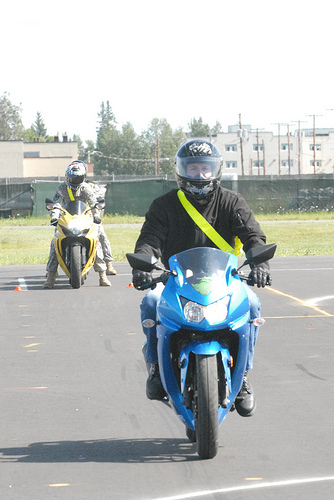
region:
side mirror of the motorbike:
[249, 245, 281, 266]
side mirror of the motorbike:
[125, 247, 160, 273]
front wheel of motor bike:
[192, 347, 230, 470]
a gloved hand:
[246, 265, 278, 291]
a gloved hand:
[132, 266, 164, 297]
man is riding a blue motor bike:
[121, 120, 287, 472]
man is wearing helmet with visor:
[174, 143, 228, 195]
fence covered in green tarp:
[237, 179, 330, 208]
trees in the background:
[100, 106, 170, 172]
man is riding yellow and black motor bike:
[45, 160, 107, 286]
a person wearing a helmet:
[172, 142, 227, 195]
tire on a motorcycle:
[186, 350, 224, 459]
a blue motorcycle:
[153, 240, 263, 462]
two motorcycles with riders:
[42, 137, 303, 430]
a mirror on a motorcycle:
[121, 251, 179, 277]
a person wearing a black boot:
[235, 371, 255, 414]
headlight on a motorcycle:
[178, 294, 230, 325]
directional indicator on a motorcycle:
[142, 315, 161, 329]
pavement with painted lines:
[285, 281, 327, 331]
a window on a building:
[280, 140, 290, 150]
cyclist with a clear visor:
[122, 134, 279, 463]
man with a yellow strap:
[124, 136, 278, 288]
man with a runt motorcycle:
[122, 131, 283, 462]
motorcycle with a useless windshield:
[123, 129, 277, 454]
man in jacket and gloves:
[125, 135, 292, 460]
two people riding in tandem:
[28, 132, 123, 299]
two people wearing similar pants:
[35, 154, 116, 296]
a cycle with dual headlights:
[119, 238, 284, 461]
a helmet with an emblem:
[160, 132, 232, 198]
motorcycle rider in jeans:
[122, 135, 290, 462]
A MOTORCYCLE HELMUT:
[171, 132, 227, 210]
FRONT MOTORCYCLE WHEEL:
[189, 343, 242, 460]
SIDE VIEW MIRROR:
[123, 248, 179, 279]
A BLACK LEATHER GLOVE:
[245, 249, 283, 289]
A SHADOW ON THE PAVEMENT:
[3, 430, 182, 474]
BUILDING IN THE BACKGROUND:
[224, 131, 330, 174]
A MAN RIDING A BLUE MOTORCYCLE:
[120, 133, 278, 467]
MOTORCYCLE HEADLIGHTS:
[179, 293, 230, 324]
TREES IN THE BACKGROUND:
[92, 91, 142, 176]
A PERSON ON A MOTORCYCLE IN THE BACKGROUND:
[34, 157, 128, 292]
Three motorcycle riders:
[22, 129, 308, 457]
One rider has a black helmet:
[121, 119, 273, 200]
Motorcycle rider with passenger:
[18, 142, 120, 289]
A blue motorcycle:
[123, 231, 300, 445]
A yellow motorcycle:
[31, 194, 118, 291]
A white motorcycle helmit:
[53, 157, 103, 190]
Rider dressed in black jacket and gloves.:
[112, 122, 296, 289]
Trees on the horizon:
[79, 97, 180, 180]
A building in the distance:
[213, 101, 333, 184]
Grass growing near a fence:
[238, 159, 333, 246]